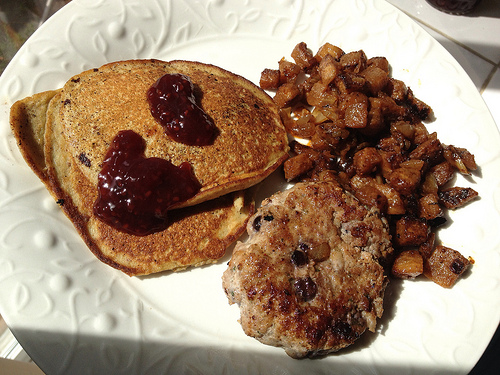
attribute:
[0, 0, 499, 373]
plate — below, white, decorated, china, decorative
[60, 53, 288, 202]
pancake — ready, roasted, numerous, breakfast, balanced, darkened, on top, short, homemade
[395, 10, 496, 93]
tile — white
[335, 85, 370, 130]
hashbrown — cooked, chopped, dark, pile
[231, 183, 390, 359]
sausage — patty, misshaped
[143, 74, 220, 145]
jam — blob, thick, dollop, large, purple, grape